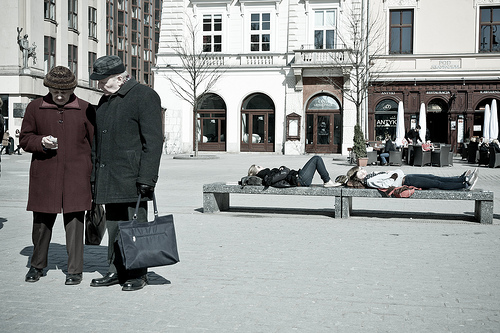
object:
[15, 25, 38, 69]
sculpture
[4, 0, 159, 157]
building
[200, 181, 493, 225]
bench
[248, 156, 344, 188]
girl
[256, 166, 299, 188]
jacket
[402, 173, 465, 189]
pants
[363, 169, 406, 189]
jacket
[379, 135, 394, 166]
person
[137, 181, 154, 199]
gloves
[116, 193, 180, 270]
satchel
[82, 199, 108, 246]
satchel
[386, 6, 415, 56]
window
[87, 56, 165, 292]
person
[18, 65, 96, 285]
person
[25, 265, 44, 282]
shoes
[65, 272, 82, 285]
shoes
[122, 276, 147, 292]
shoes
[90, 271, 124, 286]
shoes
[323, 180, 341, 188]
shoes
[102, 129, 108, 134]
button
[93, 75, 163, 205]
coat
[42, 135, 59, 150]
hand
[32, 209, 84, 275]
pants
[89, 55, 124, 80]
hat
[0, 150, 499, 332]
paved area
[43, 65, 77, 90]
hat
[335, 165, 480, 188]
people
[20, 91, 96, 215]
overcoat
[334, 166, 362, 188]
hair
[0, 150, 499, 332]
square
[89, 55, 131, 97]
head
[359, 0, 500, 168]
building